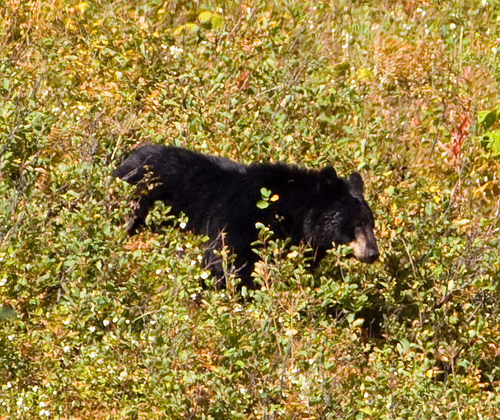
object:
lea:
[477, 104, 497, 123]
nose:
[369, 248, 377, 261]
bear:
[112, 142, 378, 308]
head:
[301, 163, 381, 264]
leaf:
[235, 357, 250, 369]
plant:
[0, 0, 500, 419]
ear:
[347, 169, 367, 195]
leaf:
[345, 310, 355, 326]